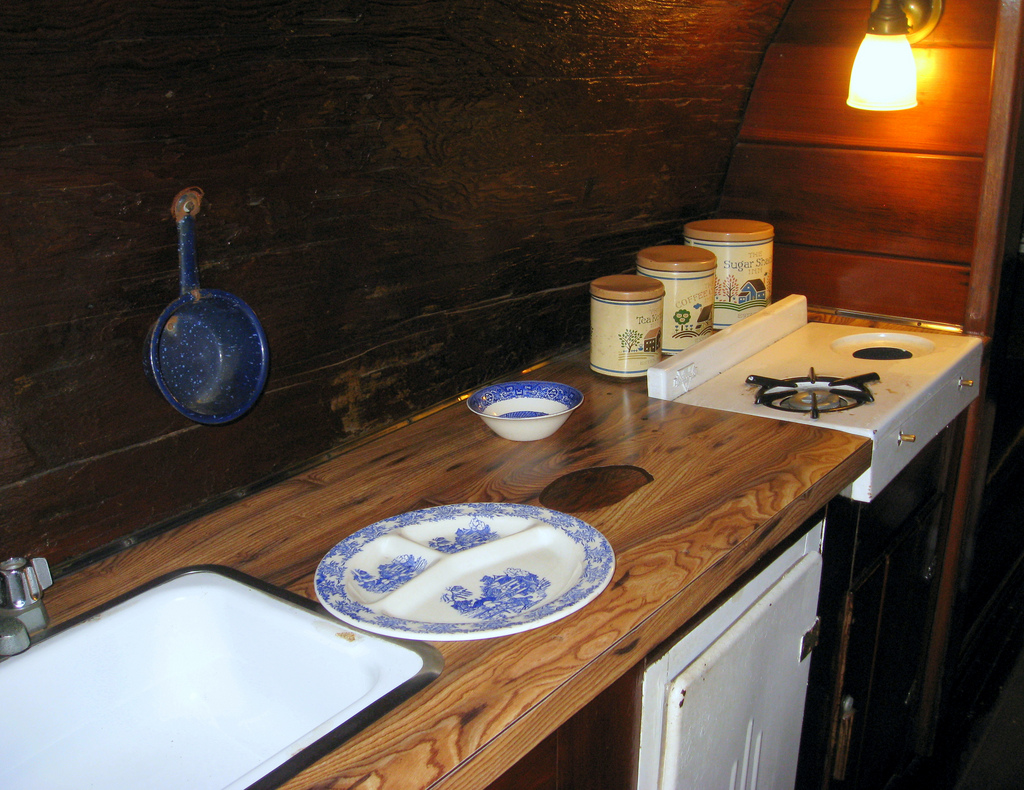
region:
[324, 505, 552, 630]
plate on the table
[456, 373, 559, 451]
bowl on the table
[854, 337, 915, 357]
burner on the stove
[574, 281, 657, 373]
can on the table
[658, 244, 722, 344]
can on the table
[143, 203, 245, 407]
pan on the shelf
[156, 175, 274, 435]
a blue pan hanging on a wall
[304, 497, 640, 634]
a blue and white plate on a counter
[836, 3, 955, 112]
a light fixture on a wall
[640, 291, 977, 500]
a small white stove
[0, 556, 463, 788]
a white sink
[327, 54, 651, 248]
a wood wall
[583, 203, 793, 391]
the canisters on counter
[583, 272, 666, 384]
a tin canister on a counter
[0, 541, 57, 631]
a silver water knob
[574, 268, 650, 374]
can on the table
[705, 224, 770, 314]
can on the table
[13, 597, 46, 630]
faucet on the sink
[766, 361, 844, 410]
burner on the stove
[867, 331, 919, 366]
burner on the stove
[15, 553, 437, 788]
A white and silver rimmed sink.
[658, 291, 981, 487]
A two range stove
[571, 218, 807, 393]
Canisters of different sizes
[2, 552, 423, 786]
the sink is white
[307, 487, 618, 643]
the plate is blue and white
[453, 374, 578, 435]
the bowl is blue and white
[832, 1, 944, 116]
the light on the wall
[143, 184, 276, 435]
the pan on the wall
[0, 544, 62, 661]
the faucet is silver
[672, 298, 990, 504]
the stovetop has 2 burners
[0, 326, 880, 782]
the countertop is wooden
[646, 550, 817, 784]
the door of the cabinet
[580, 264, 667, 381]
the smallest canister behind the stovetop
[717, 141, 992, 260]
A panel of wood.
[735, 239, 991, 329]
A panel of wood.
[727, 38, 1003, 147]
A panel of wood.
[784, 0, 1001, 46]
A panel of wood.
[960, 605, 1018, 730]
A panel of wood.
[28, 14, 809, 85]
A panel of wood.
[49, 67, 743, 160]
A panel of wood.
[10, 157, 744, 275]
A panel of wood.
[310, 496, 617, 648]
blue and white plate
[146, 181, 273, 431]
blue pot hanging on a wall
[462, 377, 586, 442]
an empty blue and white bowl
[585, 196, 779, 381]
three kitchen canisters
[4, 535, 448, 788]
kitchen sink with silver faucet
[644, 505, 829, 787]
small white refrigerator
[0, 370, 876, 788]
a wooden counter top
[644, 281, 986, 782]
small white stove top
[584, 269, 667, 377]
one cream and tan canister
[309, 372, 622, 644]
blue and white dishes on a counter